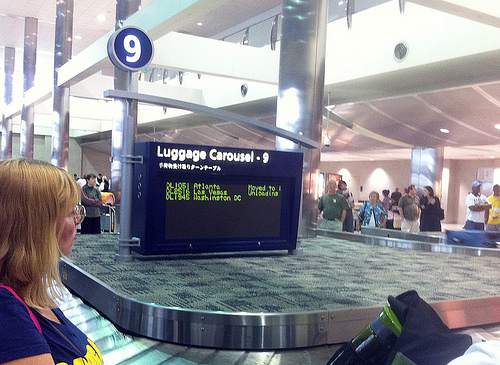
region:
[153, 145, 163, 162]
White letter on a blue sign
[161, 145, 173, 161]
White letter on a blue sign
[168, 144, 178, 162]
White letter on a blue sign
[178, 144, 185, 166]
White letter on a blue sign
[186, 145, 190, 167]
White letter on a blue sign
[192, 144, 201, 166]
White letter on a blue sign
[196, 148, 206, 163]
White letter on a blue sign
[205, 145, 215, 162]
White letter on a blue sign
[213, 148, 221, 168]
White letter on a blue sign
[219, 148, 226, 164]
White letter on a blue sign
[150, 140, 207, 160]
word luggage on sign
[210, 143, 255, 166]
word carousel on sign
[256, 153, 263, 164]
dash symbol on sign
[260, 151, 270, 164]
number nine on sign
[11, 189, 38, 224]
woman with blonde hair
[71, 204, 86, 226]
woman with glasses on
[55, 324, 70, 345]
woman wearing blue shirt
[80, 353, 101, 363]
yellow lettering on shirt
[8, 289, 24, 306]
red strap on shoulder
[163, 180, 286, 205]
green lettering on sign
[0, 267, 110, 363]
Woman wearing a shirt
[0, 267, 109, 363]
Woman is wearing a shirt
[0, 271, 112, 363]
Woman wearing a blue shirt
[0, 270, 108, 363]
Woman is wearing a blue shirt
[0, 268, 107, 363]
Woman wearing a dark blue shirt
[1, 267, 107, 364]
Woman is wearing a dark blue shirt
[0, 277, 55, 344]
Strap over woman's shoulder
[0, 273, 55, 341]
Strap is over woman's shoulder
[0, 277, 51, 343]
Pink strap over woman's shoulder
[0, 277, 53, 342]
Pink strap is over woman's shoulder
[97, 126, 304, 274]
a sign that shows the luggage terminal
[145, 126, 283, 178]
writing written in white font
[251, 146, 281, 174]
the number nine written in white font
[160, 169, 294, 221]
details written in yellow font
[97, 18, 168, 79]
the number nine in a blue circle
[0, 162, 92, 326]
the head of a woman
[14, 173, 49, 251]
the blonde hair of a woman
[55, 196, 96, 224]
the glasses of a woman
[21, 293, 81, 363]
the blue shirt of a woman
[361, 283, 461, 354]
a backpack with a cup inside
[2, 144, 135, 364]
passenger waiting for luggage to arrive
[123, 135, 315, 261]
flight status board for luggage retreival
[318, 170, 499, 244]
passengers waiting for luggage to arrive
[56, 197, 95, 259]
woman wearing glasses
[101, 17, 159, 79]
number '9' identifying pickup area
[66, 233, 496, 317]
carpeted area in middle of luggage carousel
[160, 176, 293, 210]
electronic display of individual flight information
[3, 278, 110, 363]
woman wearing blue and yellow shirt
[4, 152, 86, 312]
light colored hair of woman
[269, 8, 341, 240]
supporting beam in luggage pick up area